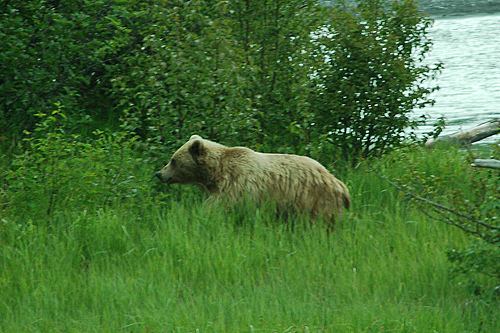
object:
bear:
[154, 134, 353, 234]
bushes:
[152, 9, 192, 138]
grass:
[0, 143, 500, 333]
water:
[401, 11, 499, 147]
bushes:
[364, 17, 387, 155]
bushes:
[105, 16, 148, 141]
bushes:
[45, 16, 67, 135]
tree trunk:
[470, 163, 499, 170]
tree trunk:
[425, 117, 500, 151]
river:
[417, 14, 500, 143]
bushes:
[2, 0, 25, 146]